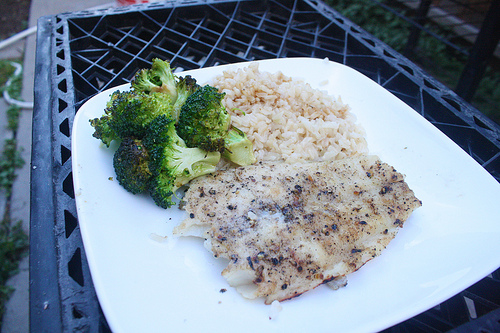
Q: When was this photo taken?
A: At meal time.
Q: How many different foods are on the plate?
A: 3.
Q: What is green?
A: The brocoli.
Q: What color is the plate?
A: White.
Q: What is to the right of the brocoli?
A: It is rice.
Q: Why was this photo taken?
A: To show the delicious food.